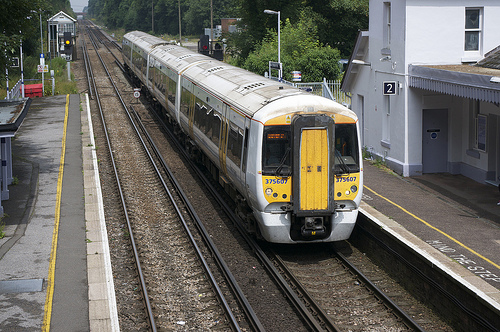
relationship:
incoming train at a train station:
[118, 27, 368, 260] [331, 1, 481, 280]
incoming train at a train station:
[118, 27, 368, 260] [336, 2, 483, 264]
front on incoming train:
[262, 109, 360, 209] [118, 29, 364, 245]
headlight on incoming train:
[343, 188, 352, 198] [118, 29, 364, 245]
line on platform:
[43, 95, 70, 331] [0, 93, 120, 331]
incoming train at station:
[118, 29, 364, 245] [1, 0, 496, 330]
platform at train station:
[355, 156, 499, 310] [1, 0, 499, 330]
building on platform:
[342, 0, 499, 193] [355, 156, 499, 310]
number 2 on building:
[387, 84, 393, 93] [342, 0, 499, 193]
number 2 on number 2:
[386, 82, 393, 94] [387, 84, 393, 93]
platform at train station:
[0, 93, 120, 331] [1, 0, 499, 330]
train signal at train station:
[64, 32, 73, 55] [1, 0, 499, 330]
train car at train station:
[180, 59, 363, 242] [1, 0, 499, 330]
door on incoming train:
[298, 126, 331, 213] [118, 29, 364, 245]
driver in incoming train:
[336, 131, 350, 151] [118, 29, 364, 245]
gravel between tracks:
[99, 45, 311, 331] [81, 45, 424, 331]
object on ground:
[20, 83, 43, 98] [0, 19, 120, 330]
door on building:
[422, 94, 452, 178] [328, 0, 498, 227]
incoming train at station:
[118, 29, 364, 245] [313, 39, 494, 281]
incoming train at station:
[118, 29, 364, 245] [328, 43, 497, 280]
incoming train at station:
[118, 29, 364, 245] [317, 63, 494, 258]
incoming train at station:
[118, 29, 364, 245] [326, 40, 497, 223]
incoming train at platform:
[118, 29, 364, 245] [360, 163, 499, 310]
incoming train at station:
[118, 29, 364, 245] [340, 21, 492, 226]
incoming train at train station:
[118, 29, 364, 245] [8, 40, 498, 320]